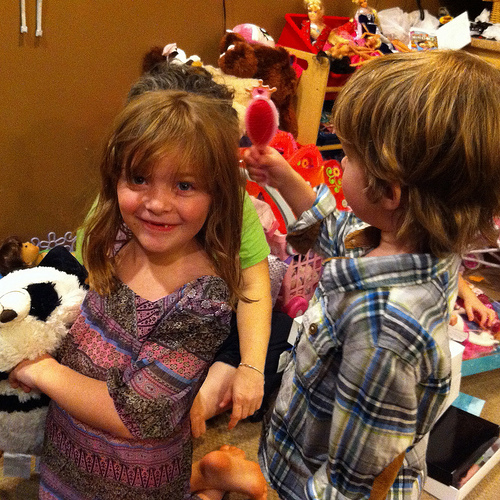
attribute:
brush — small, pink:
[244, 96, 279, 154]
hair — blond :
[333, 49, 498, 246]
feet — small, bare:
[200, 445, 267, 497]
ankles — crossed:
[190, 457, 228, 498]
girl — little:
[9, 90, 240, 496]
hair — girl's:
[62, 70, 258, 287]